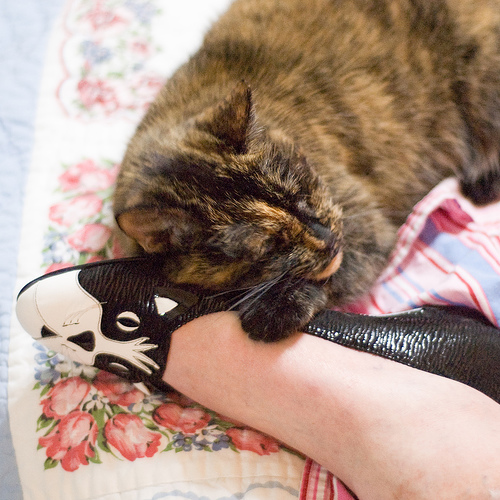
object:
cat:
[112, 2, 499, 341]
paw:
[239, 276, 331, 343]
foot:
[16, 247, 500, 499]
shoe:
[16, 247, 500, 410]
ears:
[111, 74, 261, 247]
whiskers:
[201, 268, 313, 318]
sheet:
[0, 1, 178, 284]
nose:
[302, 225, 335, 247]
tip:
[16, 278, 126, 364]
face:
[37, 282, 160, 380]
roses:
[34, 356, 287, 470]